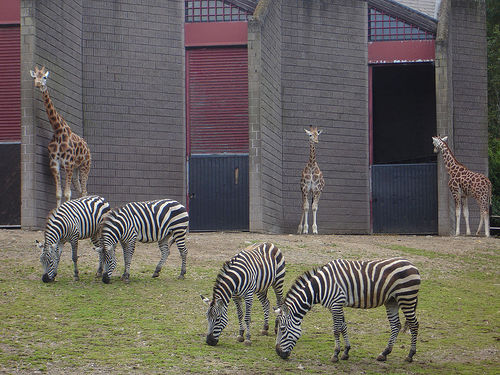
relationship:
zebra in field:
[270, 255, 422, 361] [18, 291, 198, 368]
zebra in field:
[39, 194, 116, 283] [5, 229, 481, 373]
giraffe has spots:
[426, 129, 498, 232] [457, 165, 470, 185]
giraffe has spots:
[295, 127, 327, 235] [309, 163, 319, 179]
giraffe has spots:
[27, 64, 94, 197] [65, 134, 80, 161]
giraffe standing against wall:
[430, 133, 497, 237] [27, 1, 491, 221]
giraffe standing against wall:
[295, 127, 327, 235] [0, 0, 493, 241]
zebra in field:
[270, 251, 427, 373] [5, 229, 481, 373]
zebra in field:
[191, 237, 294, 362] [5, 229, 481, 373]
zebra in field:
[86, 190, 196, 299] [5, 229, 481, 373]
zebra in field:
[31, 189, 130, 291] [5, 229, 481, 373]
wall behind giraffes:
[0, 0, 493, 241] [27, 66, 494, 235]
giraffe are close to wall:
[430, 133, 497, 237] [0, 0, 493, 241]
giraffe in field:
[430, 133, 497, 237] [14, 214, 474, 362]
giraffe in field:
[301, 127, 327, 232] [5, 229, 481, 373]